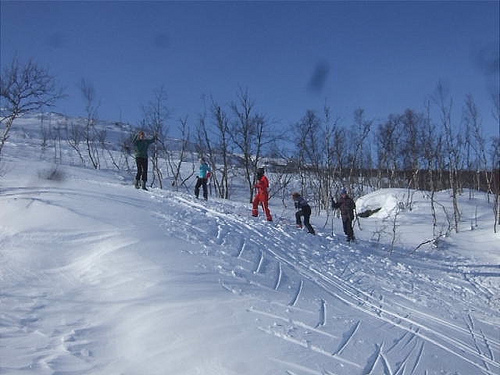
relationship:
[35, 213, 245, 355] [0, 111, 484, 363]
snow on ground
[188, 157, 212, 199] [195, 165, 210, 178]
girl in coat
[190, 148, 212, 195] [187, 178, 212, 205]
person wearing pants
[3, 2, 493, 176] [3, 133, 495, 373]
sky above hill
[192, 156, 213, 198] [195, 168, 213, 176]
person has jacket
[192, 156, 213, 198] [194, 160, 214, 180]
person wearing jacket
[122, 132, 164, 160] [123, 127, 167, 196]
snow jacket wearing person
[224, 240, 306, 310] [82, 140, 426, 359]
marks in snow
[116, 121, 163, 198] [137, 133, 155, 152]
woman wearing jacket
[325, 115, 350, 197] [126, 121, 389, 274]
tree behind people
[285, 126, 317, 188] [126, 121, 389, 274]
tree behind people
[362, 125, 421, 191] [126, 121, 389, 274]
tree behind people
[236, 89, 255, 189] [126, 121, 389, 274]
tree behind people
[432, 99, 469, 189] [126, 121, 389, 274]
tree behind people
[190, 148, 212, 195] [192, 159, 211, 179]
person wearing jacket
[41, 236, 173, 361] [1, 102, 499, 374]
sunlight on snow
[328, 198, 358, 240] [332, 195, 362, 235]
person wearing snowsuit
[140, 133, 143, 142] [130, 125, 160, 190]
head of person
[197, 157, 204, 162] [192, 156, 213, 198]
head of person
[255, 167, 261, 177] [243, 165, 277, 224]
head of person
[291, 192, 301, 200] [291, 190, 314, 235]
head of person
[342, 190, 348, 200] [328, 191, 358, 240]
head of person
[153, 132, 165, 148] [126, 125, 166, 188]
arm of man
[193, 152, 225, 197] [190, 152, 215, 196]
coat on person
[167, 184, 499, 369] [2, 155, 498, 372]
tracks in snow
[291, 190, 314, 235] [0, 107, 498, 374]
person up mountain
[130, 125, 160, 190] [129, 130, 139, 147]
person with arm up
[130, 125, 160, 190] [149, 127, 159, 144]
person with arm up